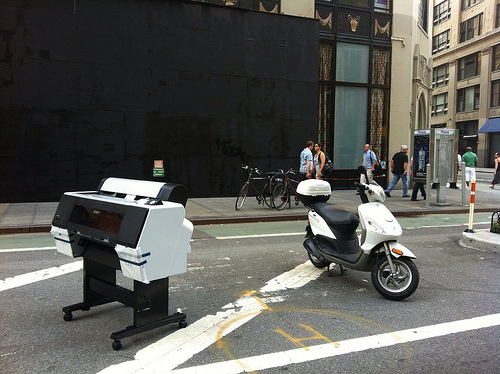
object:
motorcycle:
[295, 166, 422, 302]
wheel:
[370, 256, 419, 300]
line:
[113, 306, 499, 372]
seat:
[316, 204, 361, 231]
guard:
[356, 200, 404, 256]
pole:
[462, 176, 476, 233]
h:
[266, 321, 340, 353]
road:
[0, 207, 500, 371]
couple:
[292, 140, 328, 207]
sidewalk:
[0, 178, 499, 231]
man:
[386, 143, 409, 197]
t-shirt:
[391, 151, 410, 175]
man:
[354, 142, 379, 197]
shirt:
[360, 151, 376, 169]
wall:
[0, 1, 436, 203]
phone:
[408, 127, 456, 207]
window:
[319, 38, 390, 169]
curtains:
[371, 47, 384, 177]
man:
[461, 146, 481, 190]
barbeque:
[49, 174, 193, 353]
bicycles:
[234, 165, 289, 211]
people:
[294, 138, 317, 206]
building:
[0, 0, 434, 206]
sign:
[153, 159, 164, 178]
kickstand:
[326, 261, 351, 278]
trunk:
[294, 177, 332, 203]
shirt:
[461, 151, 480, 169]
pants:
[464, 167, 476, 185]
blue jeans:
[386, 176, 407, 195]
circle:
[210, 307, 411, 374]